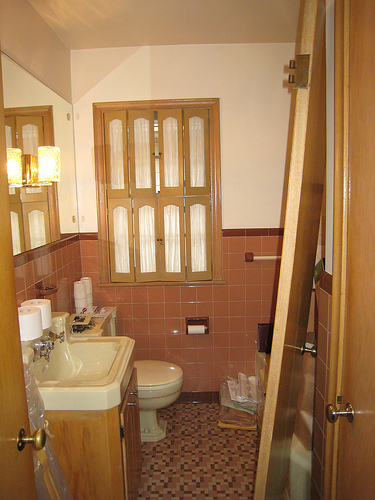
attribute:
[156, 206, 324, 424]
wall — tile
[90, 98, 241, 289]
shutters — wood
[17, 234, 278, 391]
bathroom wall — ceramic, tiled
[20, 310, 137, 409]
sink — bathroom sink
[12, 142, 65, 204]
light — bathroom light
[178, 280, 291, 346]
tiles — pink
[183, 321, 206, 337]
toilet roll — white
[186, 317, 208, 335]
toilet paper — wood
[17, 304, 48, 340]
toilet roll — white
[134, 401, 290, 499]
floor — multi colored, tile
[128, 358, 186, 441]
toilet — white, porcelain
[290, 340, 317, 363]
knob — metal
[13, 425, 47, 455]
door knob — gold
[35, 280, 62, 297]
soap dish — wood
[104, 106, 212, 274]
paneled shutters — eight paneled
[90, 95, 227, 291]
cabinet — brown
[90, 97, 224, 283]
window frame — light brown, wooden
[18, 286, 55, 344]
rolls — toilet paper rolls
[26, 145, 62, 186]
fixture — light fixture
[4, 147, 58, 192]
lights — yellow